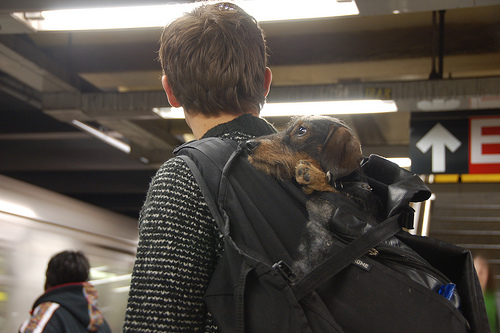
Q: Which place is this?
A: It is an airport.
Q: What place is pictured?
A: It is an airport.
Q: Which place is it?
A: It is an airport.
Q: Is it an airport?
A: Yes, it is an airport.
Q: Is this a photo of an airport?
A: Yes, it is showing an airport.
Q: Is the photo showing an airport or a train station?
A: It is showing an airport.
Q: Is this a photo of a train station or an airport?
A: It is showing an airport.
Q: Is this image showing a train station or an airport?
A: It is showing an airport.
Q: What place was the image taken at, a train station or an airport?
A: It was taken at an airport.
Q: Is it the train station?
A: No, it is the airport.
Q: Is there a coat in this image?
A: Yes, there is a coat.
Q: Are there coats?
A: Yes, there is a coat.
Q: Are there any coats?
A: Yes, there is a coat.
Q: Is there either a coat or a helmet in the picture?
A: Yes, there is a coat.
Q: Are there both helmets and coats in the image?
A: No, there is a coat but no helmets.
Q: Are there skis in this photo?
A: No, there are no skis.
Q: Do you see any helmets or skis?
A: No, there are no skis or helmets.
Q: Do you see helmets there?
A: No, there are no helmets.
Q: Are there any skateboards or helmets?
A: No, there are no helmets or skateboards.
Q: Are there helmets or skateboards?
A: No, there are no helmets or skateboards.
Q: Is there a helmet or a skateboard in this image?
A: No, there are no helmets or skateboards.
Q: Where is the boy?
A: The boy is at the airport.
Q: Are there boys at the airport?
A: Yes, there is a boy at the airport.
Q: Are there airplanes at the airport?
A: No, there is a boy at the airport.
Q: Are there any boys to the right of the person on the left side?
A: Yes, there is a boy to the right of the person.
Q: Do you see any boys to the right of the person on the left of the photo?
A: Yes, there is a boy to the right of the person.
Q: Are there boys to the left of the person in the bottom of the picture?
A: No, the boy is to the right of the person.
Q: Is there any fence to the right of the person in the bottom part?
A: No, there is a boy to the right of the person.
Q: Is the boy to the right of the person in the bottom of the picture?
A: Yes, the boy is to the right of the person.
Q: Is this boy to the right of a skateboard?
A: No, the boy is to the right of the person.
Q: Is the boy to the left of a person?
A: No, the boy is to the right of a person.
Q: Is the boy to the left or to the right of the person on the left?
A: The boy is to the right of the person.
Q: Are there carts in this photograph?
A: No, there are no carts.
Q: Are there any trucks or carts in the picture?
A: No, there are no carts or trucks.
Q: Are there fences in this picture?
A: No, there are no fences.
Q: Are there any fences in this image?
A: No, there are no fences.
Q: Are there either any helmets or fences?
A: No, there are no fences or helmets.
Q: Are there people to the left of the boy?
A: Yes, there is a person to the left of the boy.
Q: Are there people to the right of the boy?
A: No, the person is to the left of the boy.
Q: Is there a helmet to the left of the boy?
A: No, there is a person to the left of the boy.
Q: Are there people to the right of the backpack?
A: No, the person is to the left of the backpack.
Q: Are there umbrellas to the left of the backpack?
A: No, there is a person to the left of the backpack.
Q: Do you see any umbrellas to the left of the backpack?
A: No, there is a person to the left of the backpack.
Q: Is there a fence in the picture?
A: No, there are no fences.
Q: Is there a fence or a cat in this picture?
A: No, there are no fences or cats.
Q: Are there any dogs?
A: Yes, there is a dog.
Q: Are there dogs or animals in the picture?
A: Yes, there is a dog.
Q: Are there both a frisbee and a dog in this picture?
A: No, there is a dog but no frisbees.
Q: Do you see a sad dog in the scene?
A: Yes, there is a sad dog.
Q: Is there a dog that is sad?
A: Yes, there is a dog that is sad.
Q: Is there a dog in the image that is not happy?
A: Yes, there is a sad dog.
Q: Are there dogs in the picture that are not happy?
A: Yes, there is a sad dog.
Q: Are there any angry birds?
A: No, there are no angry birds.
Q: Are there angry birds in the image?
A: No, there are no angry birds.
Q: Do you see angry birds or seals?
A: No, there are no angry birds or seals.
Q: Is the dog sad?
A: Yes, the dog is sad.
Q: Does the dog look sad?
A: Yes, the dog is sad.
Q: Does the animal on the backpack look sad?
A: Yes, the dog is sad.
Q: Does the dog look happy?
A: No, the dog is sad.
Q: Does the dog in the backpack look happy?
A: No, the dog is sad.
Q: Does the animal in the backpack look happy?
A: No, the dog is sad.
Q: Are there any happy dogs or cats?
A: No, there is a dog but it is sad.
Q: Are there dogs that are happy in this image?
A: No, there is a dog but it is sad.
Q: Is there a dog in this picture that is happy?
A: No, there is a dog but it is sad.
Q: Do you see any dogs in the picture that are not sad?
A: No, there is a dog but it is sad.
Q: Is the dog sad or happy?
A: The dog is sad.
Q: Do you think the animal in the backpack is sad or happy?
A: The dog is sad.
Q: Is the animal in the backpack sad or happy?
A: The dog is sad.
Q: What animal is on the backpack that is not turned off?
A: The dog is on the backpack.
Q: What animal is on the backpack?
A: The dog is on the backpack.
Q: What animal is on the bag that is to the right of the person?
A: The animal is a dog.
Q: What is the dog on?
A: The dog is on the backpack.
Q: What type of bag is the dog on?
A: The dog is on the backpack.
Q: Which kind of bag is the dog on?
A: The dog is on the backpack.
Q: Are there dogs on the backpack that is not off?
A: Yes, there is a dog on the backpack.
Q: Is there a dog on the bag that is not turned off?
A: Yes, there is a dog on the backpack.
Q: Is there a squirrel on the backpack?
A: No, there is a dog on the backpack.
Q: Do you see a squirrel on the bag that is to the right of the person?
A: No, there is a dog on the backpack.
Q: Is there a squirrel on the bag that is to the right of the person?
A: No, there is a dog on the backpack.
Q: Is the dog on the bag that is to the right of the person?
A: Yes, the dog is on the backpack.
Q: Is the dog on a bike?
A: No, the dog is on the backpack.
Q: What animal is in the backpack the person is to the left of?
A: The dog is in the backpack.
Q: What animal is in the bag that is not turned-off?
A: The animal is a dog.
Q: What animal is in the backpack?
A: The animal is a dog.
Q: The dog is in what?
A: The dog is in the backpack.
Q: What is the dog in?
A: The dog is in the backpack.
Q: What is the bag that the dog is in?
A: The bag is a backpack.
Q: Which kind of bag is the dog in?
A: The dog is in the backpack.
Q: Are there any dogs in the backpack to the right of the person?
A: Yes, there is a dog in the backpack.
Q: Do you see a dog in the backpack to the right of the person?
A: Yes, there is a dog in the backpack.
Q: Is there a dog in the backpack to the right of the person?
A: Yes, there is a dog in the backpack.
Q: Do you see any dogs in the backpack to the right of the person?
A: Yes, there is a dog in the backpack.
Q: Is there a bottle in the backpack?
A: No, there is a dog in the backpack.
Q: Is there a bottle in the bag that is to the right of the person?
A: No, there is a dog in the backpack.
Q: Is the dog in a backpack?
A: Yes, the dog is in a backpack.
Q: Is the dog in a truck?
A: No, the dog is in a backpack.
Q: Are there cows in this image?
A: No, there are no cows.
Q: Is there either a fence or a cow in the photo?
A: No, there are no cows or fences.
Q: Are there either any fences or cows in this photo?
A: No, there are no cows or fences.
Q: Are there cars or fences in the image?
A: No, there are no cars or fences.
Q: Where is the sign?
A: The sign is at the airport.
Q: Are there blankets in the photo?
A: No, there are no blankets.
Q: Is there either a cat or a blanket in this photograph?
A: No, there are no blankets or cats.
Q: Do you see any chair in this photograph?
A: No, there are no chairs.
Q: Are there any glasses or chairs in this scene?
A: No, there are no chairs or glasses.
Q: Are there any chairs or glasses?
A: No, there are no chairs or glasses.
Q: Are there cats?
A: No, there are no cats.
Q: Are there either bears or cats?
A: No, there are no cats or bears.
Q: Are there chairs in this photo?
A: No, there are no chairs.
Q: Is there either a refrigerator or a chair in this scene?
A: No, there are no chairs or refrigerators.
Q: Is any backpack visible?
A: Yes, there is a backpack.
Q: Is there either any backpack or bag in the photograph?
A: Yes, there is a backpack.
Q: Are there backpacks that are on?
A: Yes, there is a backpack that is on.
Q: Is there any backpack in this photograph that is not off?
A: Yes, there is a backpack that is on.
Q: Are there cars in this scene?
A: No, there are no cars.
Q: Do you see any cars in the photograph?
A: No, there are no cars.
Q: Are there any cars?
A: No, there are no cars.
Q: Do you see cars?
A: No, there are no cars.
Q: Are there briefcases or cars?
A: No, there are no cars or briefcases.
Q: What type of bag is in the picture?
A: The bag is a backpack.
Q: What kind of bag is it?
A: The bag is a backpack.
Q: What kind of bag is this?
A: That is a backpack.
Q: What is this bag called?
A: That is a backpack.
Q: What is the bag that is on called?
A: The bag is a backpack.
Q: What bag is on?
A: The bag is a backpack.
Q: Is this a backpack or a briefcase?
A: This is a backpack.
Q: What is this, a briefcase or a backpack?
A: This is a backpack.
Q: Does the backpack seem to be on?
A: Yes, the backpack is on.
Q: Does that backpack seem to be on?
A: Yes, the backpack is on.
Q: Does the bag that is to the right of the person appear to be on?
A: Yes, the backpack is on.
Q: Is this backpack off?
A: No, the backpack is on.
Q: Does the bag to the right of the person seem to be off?
A: No, the backpack is on.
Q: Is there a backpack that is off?
A: No, there is a backpack but it is on.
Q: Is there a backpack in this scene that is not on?
A: No, there is a backpack but it is on.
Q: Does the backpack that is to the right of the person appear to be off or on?
A: The backpack is on.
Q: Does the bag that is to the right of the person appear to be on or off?
A: The backpack is on.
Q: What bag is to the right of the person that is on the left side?
A: The bag is a backpack.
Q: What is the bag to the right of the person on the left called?
A: The bag is a backpack.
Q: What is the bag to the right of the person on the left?
A: The bag is a backpack.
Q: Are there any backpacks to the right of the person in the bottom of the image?
A: Yes, there is a backpack to the right of the person.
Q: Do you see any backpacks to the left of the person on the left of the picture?
A: No, the backpack is to the right of the person.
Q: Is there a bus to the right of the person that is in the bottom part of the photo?
A: No, there is a backpack to the right of the person.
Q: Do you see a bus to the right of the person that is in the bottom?
A: No, there is a backpack to the right of the person.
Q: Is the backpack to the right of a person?
A: Yes, the backpack is to the right of a person.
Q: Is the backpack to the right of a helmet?
A: No, the backpack is to the right of a person.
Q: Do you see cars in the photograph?
A: No, there are no cars.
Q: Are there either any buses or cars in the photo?
A: No, there are no cars or buses.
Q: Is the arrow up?
A: Yes, the arrow is up.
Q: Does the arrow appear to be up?
A: Yes, the arrow is up.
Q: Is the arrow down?
A: No, the arrow is up.